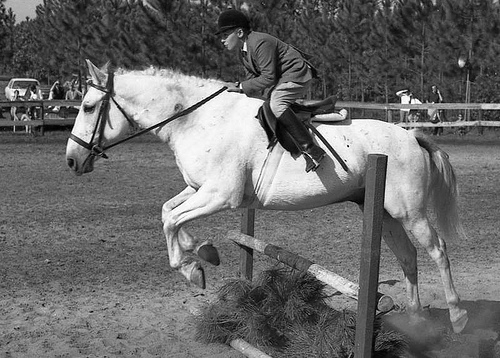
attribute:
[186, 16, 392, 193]
jockey — leaning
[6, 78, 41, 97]
car — white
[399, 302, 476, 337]
hooves — horse's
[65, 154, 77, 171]
nostril — large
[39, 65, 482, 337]
horse — white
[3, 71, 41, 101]
car — white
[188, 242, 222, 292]
hooves — sturdy, black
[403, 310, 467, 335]
hooves — sturdy, black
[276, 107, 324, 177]
boot — black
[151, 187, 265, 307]
legs — bent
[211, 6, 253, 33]
helmet — black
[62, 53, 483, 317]
horse — white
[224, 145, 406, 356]
fence — wooden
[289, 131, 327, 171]
boots — black